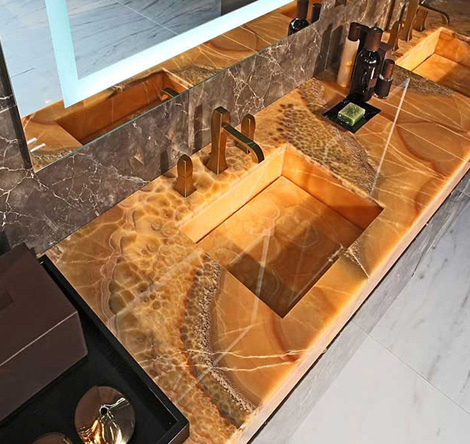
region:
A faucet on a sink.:
[170, 106, 265, 198]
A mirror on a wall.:
[3, 0, 323, 174]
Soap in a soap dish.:
[320, 93, 382, 134]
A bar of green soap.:
[336, 100, 366, 127]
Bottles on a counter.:
[335, 22, 396, 103]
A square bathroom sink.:
[172, 141, 384, 319]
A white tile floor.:
[248, 170, 466, 443]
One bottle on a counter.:
[336, 21, 362, 88]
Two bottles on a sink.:
[336, 21, 384, 104]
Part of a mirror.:
[3, 0, 322, 173]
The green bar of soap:
[335, 100, 369, 125]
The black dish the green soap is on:
[319, 92, 385, 136]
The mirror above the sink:
[1, 0, 338, 179]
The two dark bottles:
[352, 20, 403, 99]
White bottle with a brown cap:
[333, 19, 366, 87]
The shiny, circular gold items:
[20, 380, 137, 443]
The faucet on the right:
[381, 0, 451, 55]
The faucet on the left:
[168, 102, 268, 201]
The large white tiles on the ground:
[249, 171, 469, 442]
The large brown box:
[0, 240, 89, 417]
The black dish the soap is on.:
[324, 94, 367, 123]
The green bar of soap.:
[341, 100, 363, 124]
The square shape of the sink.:
[178, 148, 342, 303]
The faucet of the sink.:
[214, 106, 260, 170]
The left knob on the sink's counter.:
[173, 153, 194, 186]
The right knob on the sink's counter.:
[239, 104, 263, 145]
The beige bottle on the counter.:
[338, 18, 358, 93]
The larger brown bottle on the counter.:
[352, 27, 378, 97]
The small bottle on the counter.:
[380, 63, 394, 97]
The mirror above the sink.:
[5, 2, 331, 157]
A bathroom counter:
[45, 10, 467, 442]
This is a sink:
[173, 104, 389, 323]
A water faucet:
[171, 103, 269, 198]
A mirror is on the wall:
[0, 0, 329, 173]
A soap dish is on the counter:
[322, 91, 384, 135]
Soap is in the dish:
[335, 100, 367, 126]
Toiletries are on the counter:
[334, 18, 396, 101]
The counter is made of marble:
[40, 14, 468, 442]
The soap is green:
[336, 100, 367, 125]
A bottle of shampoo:
[333, 20, 362, 93]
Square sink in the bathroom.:
[162, 142, 378, 322]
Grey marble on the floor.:
[247, 169, 468, 441]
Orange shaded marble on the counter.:
[52, 23, 466, 443]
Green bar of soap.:
[338, 101, 367, 124]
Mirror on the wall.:
[0, 2, 326, 175]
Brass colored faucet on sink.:
[156, 103, 270, 200]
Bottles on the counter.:
[339, 21, 397, 100]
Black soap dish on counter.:
[320, 91, 382, 135]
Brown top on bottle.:
[362, 23, 383, 54]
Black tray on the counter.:
[1, 243, 193, 442]